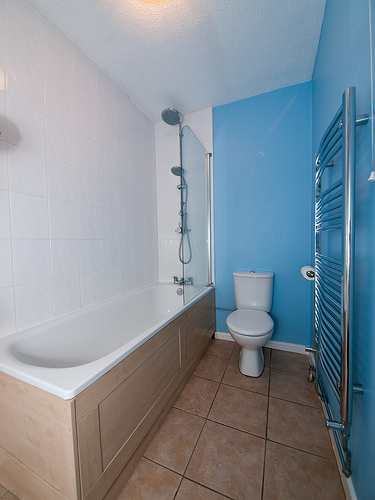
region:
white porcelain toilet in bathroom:
[226, 268, 276, 379]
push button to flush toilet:
[248, 270, 257, 275]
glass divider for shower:
[180, 124, 212, 305]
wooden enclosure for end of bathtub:
[0, 373, 73, 499]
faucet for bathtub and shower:
[168, 275, 194, 286]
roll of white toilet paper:
[298, 264, 314, 280]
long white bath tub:
[0, 273, 214, 401]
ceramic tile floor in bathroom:
[116, 333, 343, 498]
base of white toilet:
[225, 308, 274, 379]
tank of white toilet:
[232, 267, 274, 313]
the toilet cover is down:
[221, 304, 284, 372]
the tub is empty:
[13, 278, 224, 375]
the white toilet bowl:
[225, 270, 274, 378]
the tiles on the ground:
[0, 337, 346, 498]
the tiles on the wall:
[0, 0, 212, 339]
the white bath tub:
[1, 282, 212, 398]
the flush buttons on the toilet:
[249, 269, 255, 273]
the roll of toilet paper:
[301, 264, 314, 280]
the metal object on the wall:
[305, 86, 368, 477]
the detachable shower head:
[170, 165, 191, 264]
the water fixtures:
[170, 275, 192, 286]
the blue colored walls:
[211, 34, 374, 497]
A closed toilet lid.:
[225, 307, 280, 339]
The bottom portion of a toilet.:
[229, 345, 268, 376]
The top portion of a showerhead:
[146, 96, 187, 131]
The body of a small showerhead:
[170, 183, 190, 262]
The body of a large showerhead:
[164, 128, 192, 166]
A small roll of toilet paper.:
[297, 259, 314, 284]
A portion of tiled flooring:
[180, 383, 304, 493]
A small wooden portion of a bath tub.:
[2, 395, 74, 483]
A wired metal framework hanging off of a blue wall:
[314, 81, 348, 441]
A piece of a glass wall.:
[180, 125, 212, 305]